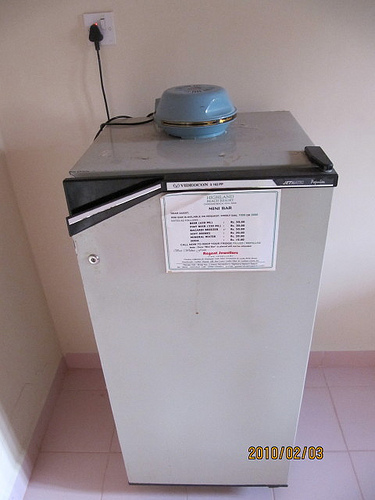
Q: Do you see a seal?
A: Yes, there is a seal.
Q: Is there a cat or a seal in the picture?
A: Yes, there is a seal.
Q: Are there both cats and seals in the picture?
A: No, there is a seal but no cats.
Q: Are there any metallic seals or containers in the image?
A: Yes, there is a metal seal.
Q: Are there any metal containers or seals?
A: Yes, there is a metal seal.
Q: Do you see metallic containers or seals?
A: Yes, there is a metal seal.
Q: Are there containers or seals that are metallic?
A: Yes, the seal is metallic.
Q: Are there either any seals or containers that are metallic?
A: Yes, the seal is metallic.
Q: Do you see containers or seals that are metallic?
A: Yes, the seal is metallic.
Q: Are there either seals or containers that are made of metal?
A: Yes, the seal is made of metal.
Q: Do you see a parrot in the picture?
A: No, there are no parrots.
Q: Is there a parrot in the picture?
A: No, there are no parrots.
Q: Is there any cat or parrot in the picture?
A: No, there are no parrots or cats.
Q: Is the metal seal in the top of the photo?
A: Yes, the seal is in the top of the image.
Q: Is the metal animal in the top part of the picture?
A: Yes, the seal is in the top of the image.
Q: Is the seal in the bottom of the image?
A: No, the seal is in the top of the image.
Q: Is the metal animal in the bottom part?
A: No, the seal is in the top of the image.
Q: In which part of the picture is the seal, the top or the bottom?
A: The seal is in the top of the image.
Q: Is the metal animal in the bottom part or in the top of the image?
A: The seal is in the top of the image.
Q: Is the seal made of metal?
A: Yes, the seal is made of metal.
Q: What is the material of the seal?
A: The seal is made of metal.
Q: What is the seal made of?
A: The seal is made of metal.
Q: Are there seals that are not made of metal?
A: No, there is a seal but it is made of metal.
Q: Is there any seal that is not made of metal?
A: No, there is a seal but it is made of metal.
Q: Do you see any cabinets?
A: No, there are no cabinets.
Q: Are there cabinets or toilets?
A: No, there are no cabinets or toilets.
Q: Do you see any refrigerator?
A: Yes, there is a refrigerator.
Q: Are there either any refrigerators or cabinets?
A: Yes, there is a refrigerator.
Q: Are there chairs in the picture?
A: No, there are no chairs.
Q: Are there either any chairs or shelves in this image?
A: No, there are no chairs or shelves.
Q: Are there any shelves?
A: No, there are no shelves.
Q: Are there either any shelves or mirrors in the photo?
A: No, there are no shelves or mirrors.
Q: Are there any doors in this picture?
A: Yes, there is a door.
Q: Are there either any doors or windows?
A: Yes, there is a door.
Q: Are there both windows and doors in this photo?
A: No, there is a door but no windows.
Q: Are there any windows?
A: No, there are no windows.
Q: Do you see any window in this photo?
A: No, there are no windows.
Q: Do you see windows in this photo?
A: No, there are no windows.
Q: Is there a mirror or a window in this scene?
A: No, there are no windows or mirrors.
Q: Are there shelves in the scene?
A: No, there are no shelves.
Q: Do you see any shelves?
A: No, there are no shelves.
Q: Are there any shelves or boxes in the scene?
A: No, there are no shelves or boxes.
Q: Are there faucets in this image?
A: No, there are no faucets.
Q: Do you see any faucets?
A: No, there are no faucets.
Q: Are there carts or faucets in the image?
A: No, there are no faucets or carts.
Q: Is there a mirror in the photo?
A: No, there are no mirrors.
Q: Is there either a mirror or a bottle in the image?
A: No, there are no mirrors or bottles.